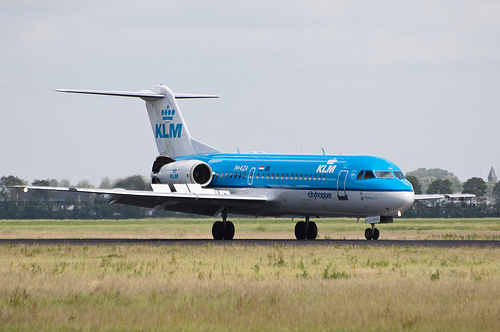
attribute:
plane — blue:
[36, 55, 486, 234]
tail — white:
[54, 68, 238, 162]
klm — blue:
[151, 122, 183, 143]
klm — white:
[315, 164, 341, 177]